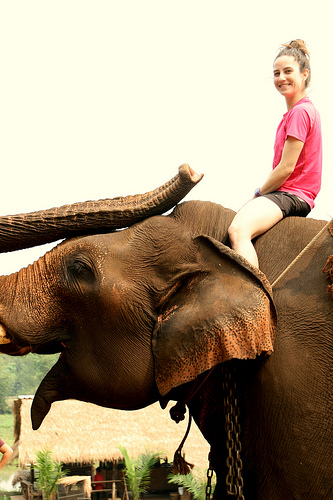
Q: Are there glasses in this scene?
A: No, there are no glasses.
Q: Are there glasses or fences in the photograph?
A: No, there are no glasses or fences.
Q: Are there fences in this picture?
A: No, there are no fences.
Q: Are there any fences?
A: No, there are no fences.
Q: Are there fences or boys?
A: No, there are no fences or boys.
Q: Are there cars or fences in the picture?
A: No, there are no fences or cars.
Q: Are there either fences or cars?
A: No, there are no fences or cars.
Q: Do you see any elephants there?
A: Yes, there is an elephant.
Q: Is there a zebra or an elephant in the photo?
A: Yes, there is an elephant.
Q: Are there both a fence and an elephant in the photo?
A: No, there is an elephant but no fences.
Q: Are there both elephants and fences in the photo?
A: No, there is an elephant but no fences.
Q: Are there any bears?
A: No, there are no bears.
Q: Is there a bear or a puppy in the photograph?
A: No, there are no bears or puppys.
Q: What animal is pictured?
A: The animal is an elephant.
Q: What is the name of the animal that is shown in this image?
A: The animal is an elephant.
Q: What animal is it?
A: The animal is an elephant.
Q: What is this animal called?
A: This is an elephant.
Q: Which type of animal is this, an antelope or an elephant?
A: This is an elephant.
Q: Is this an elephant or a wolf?
A: This is an elephant.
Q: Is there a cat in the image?
A: No, there are no cats.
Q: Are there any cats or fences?
A: No, there are no cats or fences.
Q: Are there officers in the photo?
A: No, there are no officers.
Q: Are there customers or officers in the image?
A: No, there are no officers or customers.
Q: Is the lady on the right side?
A: Yes, the lady is on the right of the image.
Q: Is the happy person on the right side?
A: Yes, the lady is on the right of the image.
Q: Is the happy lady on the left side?
A: No, the lady is on the right of the image.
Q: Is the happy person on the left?
A: No, the lady is on the right of the image.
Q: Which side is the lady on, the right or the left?
A: The lady is on the right of the image.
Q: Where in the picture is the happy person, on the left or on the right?
A: The lady is on the right of the image.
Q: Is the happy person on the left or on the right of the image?
A: The lady is on the right of the image.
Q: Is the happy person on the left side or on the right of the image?
A: The lady is on the right of the image.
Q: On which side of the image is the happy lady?
A: The lady is on the right of the image.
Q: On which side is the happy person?
A: The lady is on the right of the image.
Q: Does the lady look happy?
A: Yes, the lady is happy.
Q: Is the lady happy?
A: Yes, the lady is happy.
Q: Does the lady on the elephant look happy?
A: Yes, the lady is happy.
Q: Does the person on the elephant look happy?
A: Yes, the lady is happy.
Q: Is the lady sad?
A: No, the lady is happy.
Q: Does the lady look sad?
A: No, the lady is happy.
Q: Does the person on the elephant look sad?
A: No, the lady is happy.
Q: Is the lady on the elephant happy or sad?
A: The lady is happy.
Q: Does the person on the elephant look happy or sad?
A: The lady is happy.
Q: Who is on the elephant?
A: The lady is on the elephant.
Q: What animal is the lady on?
A: The lady is on the elephant.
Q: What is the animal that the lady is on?
A: The animal is an elephant.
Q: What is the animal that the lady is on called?
A: The animal is an elephant.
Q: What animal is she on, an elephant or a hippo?
A: The lady is on an elephant.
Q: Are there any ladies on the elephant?
A: Yes, there is a lady on the elephant.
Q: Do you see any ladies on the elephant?
A: Yes, there is a lady on the elephant.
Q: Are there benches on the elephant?
A: No, there is a lady on the elephant.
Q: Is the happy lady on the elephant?
A: Yes, the lady is on the elephant.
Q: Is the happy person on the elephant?
A: Yes, the lady is on the elephant.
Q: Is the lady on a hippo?
A: No, the lady is on the elephant.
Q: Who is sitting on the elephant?
A: The lady is sitting on the elephant.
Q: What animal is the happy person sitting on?
A: The lady is sitting on the elephant.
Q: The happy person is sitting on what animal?
A: The lady is sitting on the elephant.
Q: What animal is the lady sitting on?
A: The lady is sitting on the elephant.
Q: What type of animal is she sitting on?
A: The lady is sitting on the elephant.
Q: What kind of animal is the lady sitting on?
A: The lady is sitting on the elephant.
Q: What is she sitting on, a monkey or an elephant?
A: The lady is sitting on an elephant.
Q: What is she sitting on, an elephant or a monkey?
A: The lady is sitting on an elephant.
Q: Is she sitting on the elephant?
A: Yes, the lady is sitting on the elephant.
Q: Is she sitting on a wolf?
A: No, the lady is sitting on the elephant.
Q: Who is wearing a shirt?
A: The lady is wearing a shirt.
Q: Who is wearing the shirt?
A: The lady is wearing a shirt.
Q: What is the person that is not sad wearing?
A: The lady is wearing a shirt.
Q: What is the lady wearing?
A: The lady is wearing a shirt.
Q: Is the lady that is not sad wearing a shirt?
A: Yes, the lady is wearing a shirt.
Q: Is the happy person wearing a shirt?
A: Yes, the lady is wearing a shirt.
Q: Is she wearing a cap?
A: No, the lady is wearing a shirt.